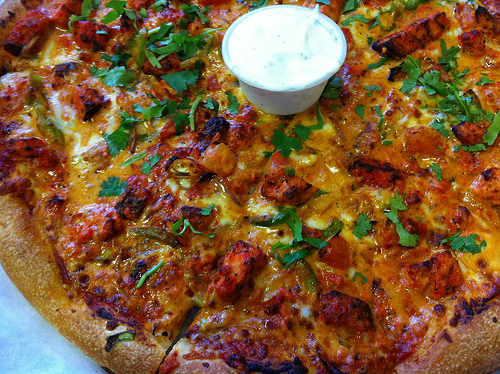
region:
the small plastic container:
[221, 5, 346, 115]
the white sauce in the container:
[222, 3, 347, 113]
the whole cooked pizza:
[0, 0, 498, 372]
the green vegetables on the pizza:
[67, 0, 498, 352]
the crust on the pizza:
[0, 0, 498, 372]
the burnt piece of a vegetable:
[105, 328, 136, 351]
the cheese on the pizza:
[0, 0, 497, 372]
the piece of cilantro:
[352, 211, 371, 239]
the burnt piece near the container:
[196, 114, 228, 136]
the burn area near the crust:
[227, 351, 350, 371]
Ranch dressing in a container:
[220, 2, 348, 117]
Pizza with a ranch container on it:
[0, 0, 497, 372]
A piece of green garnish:
[382, 190, 421, 247]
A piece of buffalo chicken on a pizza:
[212, 237, 264, 302]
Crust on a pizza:
[1, 188, 170, 370]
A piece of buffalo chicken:
[319, 289, 374, 331]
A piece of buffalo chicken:
[260, 163, 318, 209]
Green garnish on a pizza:
[395, 38, 498, 156]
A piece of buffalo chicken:
[371, 10, 450, 59]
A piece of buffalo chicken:
[3, 7, 53, 57]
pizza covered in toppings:
[1, 2, 498, 364]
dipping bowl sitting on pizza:
[214, 6, 343, 112]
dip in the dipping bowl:
[227, 4, 331, 67]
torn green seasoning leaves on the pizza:
[62, 2, 498, 279]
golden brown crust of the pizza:
[5, 188, 477, 372]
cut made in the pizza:
[118, 239, 235, 372]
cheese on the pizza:
[15, 6, 495, 356]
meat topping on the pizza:
[18, 4, 497, 361]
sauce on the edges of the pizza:
[1, 4, 462, 373]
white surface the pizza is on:
[2, 279, 105, 372]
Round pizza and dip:
[4, 5, 498, 369]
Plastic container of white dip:
[216, 4, 348, 119]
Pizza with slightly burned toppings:
[3, 5, 494, 366]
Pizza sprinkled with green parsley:
[0, 1, 490, 366]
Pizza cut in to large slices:
[4, 2, 495, 372]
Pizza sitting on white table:
[2, 2, 497, 372]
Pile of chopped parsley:
[61, 5, 237, 167]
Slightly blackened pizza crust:
[162, 324, 381, 371]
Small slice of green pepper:
[19, 71, 69, 145]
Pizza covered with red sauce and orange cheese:
[4, 4, 499, 371]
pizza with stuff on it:
[2, 0, 496, 372]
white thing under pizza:
[0, 268, 103, 373]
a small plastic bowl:
[221, 5, 346, 114]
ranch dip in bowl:
[223, 4, 343, 113]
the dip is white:
[227, 4, 336, 84]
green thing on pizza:
[274, 206, 303, 241]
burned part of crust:
[97, 305, 119, 327]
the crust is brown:
[1, 198, 166, 373]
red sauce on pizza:
[0, 3, 499, 372]